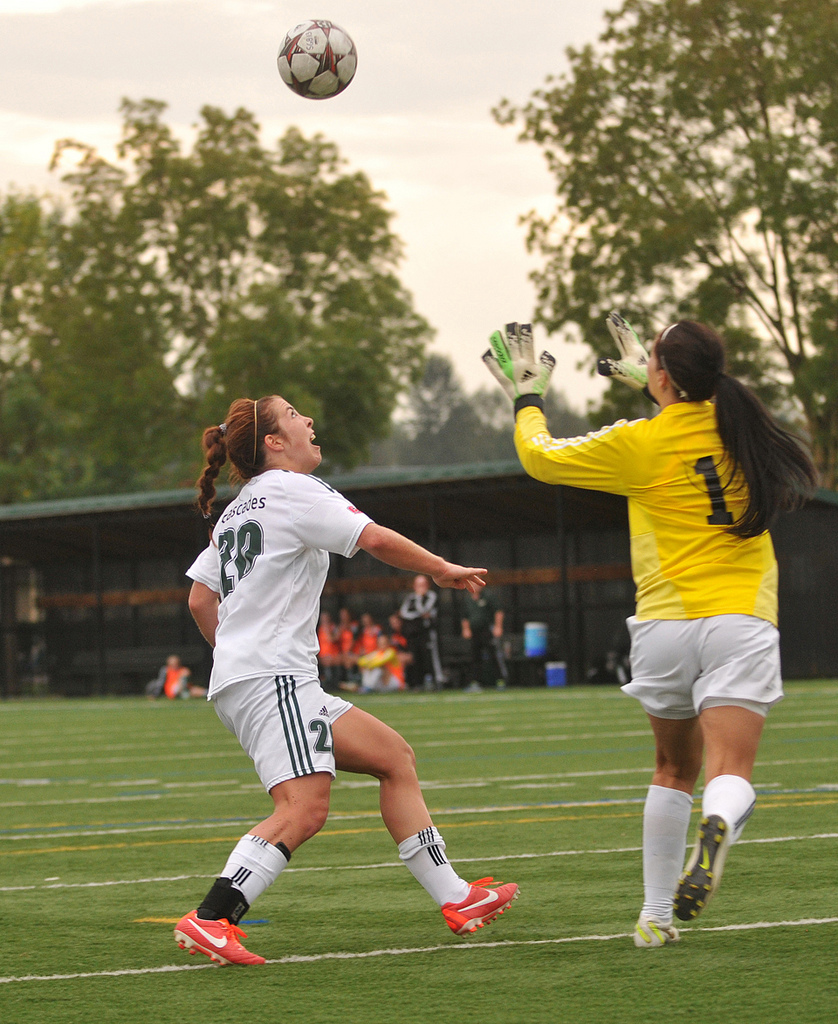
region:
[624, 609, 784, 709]
a pair of white shorts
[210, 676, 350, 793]
a pair of white printed shorts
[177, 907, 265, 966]
an orange cleated athletic shoe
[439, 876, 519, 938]
an orange cleated athletic shoe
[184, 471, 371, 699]
a white soccer jersey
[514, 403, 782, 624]
a yellow soccer jersey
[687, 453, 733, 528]
printed player number 1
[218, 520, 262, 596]
printed player number 20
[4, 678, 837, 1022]
a marked green soccer field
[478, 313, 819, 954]
a soccer player reaching upwards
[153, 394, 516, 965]
the soccer player in the white uniform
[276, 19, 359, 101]
the soccer ball in the air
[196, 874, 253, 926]
the black anke brace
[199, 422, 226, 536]
the red pony tail on the woman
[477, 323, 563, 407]
the glove on the player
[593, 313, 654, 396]
the glove on the player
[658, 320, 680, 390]
the white band in the players hair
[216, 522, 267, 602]
the numbe ron the back of the jersey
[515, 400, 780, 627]
the yellow jersey on the player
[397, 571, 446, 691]
the coach in the black and white suit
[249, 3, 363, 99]
red and white soccer ball in air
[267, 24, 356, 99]
red and white soccer ball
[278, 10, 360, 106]
soccer ball in air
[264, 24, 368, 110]
white soccer ball in air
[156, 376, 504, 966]
young woman playing soccer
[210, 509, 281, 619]
number on back of uniform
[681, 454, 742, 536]
number on back of uniform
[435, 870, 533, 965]
red and white shoe worn by young woman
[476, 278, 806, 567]
woman wearing big gloves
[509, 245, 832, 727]
woman wearing yellow shirt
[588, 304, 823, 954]
woman wearing white shorts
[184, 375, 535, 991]
woman wearing white shirt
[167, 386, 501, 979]
woman wearing white shorts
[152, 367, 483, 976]
woman wearing white socks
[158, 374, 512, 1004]
woman wearing orange shoes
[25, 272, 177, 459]
trees near soccer field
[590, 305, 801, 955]
woman wearing white socks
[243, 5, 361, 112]
red and white soccer ball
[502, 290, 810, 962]
young woman playing soccer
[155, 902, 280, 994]
red and white soccer shoe worn by young woman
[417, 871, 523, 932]
red and white soccer shoe worn by young woman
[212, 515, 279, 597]
number on white uniform shirt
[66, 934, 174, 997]
white stripes on green soccer field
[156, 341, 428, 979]
A woman looking up at a ball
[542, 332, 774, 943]
A woman trying to catch a ball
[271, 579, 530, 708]
A group of people watching a soccer game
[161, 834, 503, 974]
A girl was orange and white shoes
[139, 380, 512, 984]
A person is playing.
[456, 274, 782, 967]
A person is standing up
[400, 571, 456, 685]
A person is standing up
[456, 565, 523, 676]
A person is standing up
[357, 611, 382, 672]
A person is standing up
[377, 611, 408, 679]
A person is standing up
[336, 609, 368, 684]
A person is standing up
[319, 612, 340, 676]
A person is standing up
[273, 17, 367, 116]
Soccer ball in the air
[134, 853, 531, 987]
A pair of red shoes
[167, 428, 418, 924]
A woman playing soccer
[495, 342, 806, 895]
A woman wearing a yellow shirt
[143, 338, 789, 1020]
Two people playing a game of soccer